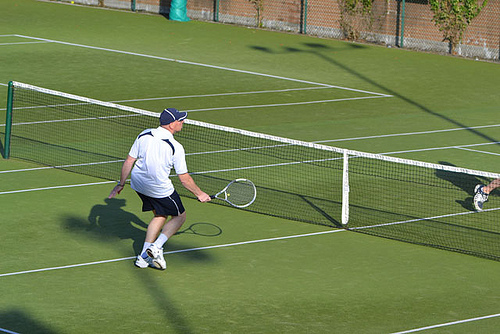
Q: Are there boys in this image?
A: No, there are no boys.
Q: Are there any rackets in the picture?
A: Yes, there is a racket.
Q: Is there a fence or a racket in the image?
A: Yes, there is a racket.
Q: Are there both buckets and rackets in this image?
A: No, there is a racket but no buckets.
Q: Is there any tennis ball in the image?
A: No, there are no tennis balls.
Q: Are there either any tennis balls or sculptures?
A: No, there are no tennis balls or sculptures.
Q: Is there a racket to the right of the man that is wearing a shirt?
A: Yes, there is a racket to the right of the man.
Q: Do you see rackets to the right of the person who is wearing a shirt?
A: Yes, there is a racket to the right of the man.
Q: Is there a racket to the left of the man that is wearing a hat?
A: No, the racket is to the right of the man.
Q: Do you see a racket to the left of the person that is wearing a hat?
A: No, the racket is to the right of the man.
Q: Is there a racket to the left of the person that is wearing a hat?
A: No, the racket is to the right of the man.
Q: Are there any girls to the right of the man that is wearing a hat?
A: No, there is a racket to the right of the man.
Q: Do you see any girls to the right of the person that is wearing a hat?
A: No, there is a racket to the right of the man.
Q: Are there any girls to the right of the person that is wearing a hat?
A: No, there is a racket to the right of the man.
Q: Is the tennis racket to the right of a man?
A: Yes, the tennis racket is to the right of a man.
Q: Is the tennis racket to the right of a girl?
A: No, the tennis racket is to the right of a man.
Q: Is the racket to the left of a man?
A: No, the racket is to the right of a man.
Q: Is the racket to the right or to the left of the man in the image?
A: The racket is to the right of the man.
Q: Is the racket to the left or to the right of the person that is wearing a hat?
A: The racket is to the right of the man.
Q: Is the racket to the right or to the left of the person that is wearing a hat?
A: The racket is to the right of the man.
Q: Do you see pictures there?
A: No, there are no pictures.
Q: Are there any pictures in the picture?
A: No, there are no pictures.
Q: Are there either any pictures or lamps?
A: No, there are no pictures or lamps.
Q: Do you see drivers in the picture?
A: No, there are no drivers.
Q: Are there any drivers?
A: No, there are no drivers.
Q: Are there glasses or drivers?
A: No, there are no drivers or glasses.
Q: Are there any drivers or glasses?
A: No, there are no drivers or glasses.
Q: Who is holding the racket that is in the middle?
A: The man is holding the tennis racket.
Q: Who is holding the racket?
A: The man is holding the tennis racket.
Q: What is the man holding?
A: The man is holding the tennis racket.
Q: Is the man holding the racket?
A: Yes, the man is holding the racket.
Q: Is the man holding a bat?
A: No, the man is holding the racket.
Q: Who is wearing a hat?
A: The man is wearing a hat.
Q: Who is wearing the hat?
A: The man is wearing a hat.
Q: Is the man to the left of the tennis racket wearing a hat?
A: Yes, the man is wearing a hat.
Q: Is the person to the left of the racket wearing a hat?
A: Yes, the man is wearing a hat.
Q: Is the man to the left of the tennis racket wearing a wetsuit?
A: No, the man is wearing a hat.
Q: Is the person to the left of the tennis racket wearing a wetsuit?
A: No, the man is wearing a hat.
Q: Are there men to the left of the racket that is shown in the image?
A: Yes, there is a man to the left of the racket.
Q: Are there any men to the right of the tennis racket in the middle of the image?
A: No, the man is to the left of the racket.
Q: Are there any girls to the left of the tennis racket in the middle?
A: No, there is a man to the left of the tennis racket.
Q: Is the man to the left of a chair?
A: No, the man is to the left of the tennis racket.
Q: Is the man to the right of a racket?
A: No, the man is to the left of a racket.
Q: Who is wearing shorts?
A: The man is wearing shorts.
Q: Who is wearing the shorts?
A: The man is wearing shorts.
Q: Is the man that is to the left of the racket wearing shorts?
A: Yes, the man is wearing shorts.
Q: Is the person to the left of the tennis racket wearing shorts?
A: Yes, the man is wearing shorts.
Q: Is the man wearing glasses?
A: No, the man is wearing shorts.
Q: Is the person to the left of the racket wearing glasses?
A: No, the man is wearing shorts.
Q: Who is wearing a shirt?
A: The man is wearing a shirt.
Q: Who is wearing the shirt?
A: The man is wearing a shirt.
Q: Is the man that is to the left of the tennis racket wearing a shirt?
A: Yes, the man is wearing a shirt.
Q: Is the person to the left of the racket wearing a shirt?
A: Yes, the man is wearing a shirt.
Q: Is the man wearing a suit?
A: No, the man is wearing a shirt.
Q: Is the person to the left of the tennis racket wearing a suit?
A: No, the man is wearing a shirt.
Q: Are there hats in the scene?
A: Yes, there is a hat.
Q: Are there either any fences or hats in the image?
A: Yes, there is a hat.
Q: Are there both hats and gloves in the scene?
A: No, there is a hat but no gloves.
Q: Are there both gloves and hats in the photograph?
A: No, there is a hat but no gloves.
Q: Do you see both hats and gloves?
A: No, there is a hat but no gloves.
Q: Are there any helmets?
A: No, there are no helmets.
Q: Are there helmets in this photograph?
A: No, there are no helmets.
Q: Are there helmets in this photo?
A: No, there are no helmets.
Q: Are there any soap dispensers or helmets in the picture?
A: No, there are no helmets or soap dispensers.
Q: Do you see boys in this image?
A: No, there are no boys.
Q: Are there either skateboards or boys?
A: No, there are no boys or skateboards.